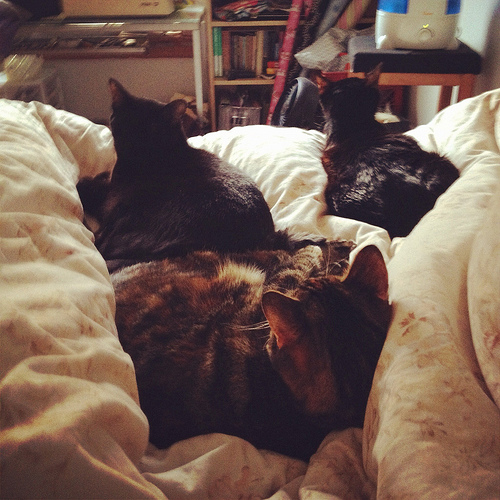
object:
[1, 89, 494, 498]
bed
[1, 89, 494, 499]
room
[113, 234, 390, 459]
cat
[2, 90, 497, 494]
blanket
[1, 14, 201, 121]
wall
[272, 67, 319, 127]
fan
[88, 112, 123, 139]
floor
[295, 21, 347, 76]
paper rolls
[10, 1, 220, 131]
desk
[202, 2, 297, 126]
bookcase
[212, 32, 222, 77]
books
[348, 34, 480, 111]
table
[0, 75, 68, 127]
storage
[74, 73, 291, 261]
cat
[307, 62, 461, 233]
cat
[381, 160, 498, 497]
comforter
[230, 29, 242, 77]
books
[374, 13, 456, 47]
humidifier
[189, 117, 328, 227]
bed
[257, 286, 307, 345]
ear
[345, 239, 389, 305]
ear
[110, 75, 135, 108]
ear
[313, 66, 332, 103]
ear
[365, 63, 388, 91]
ear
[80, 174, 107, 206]
paw